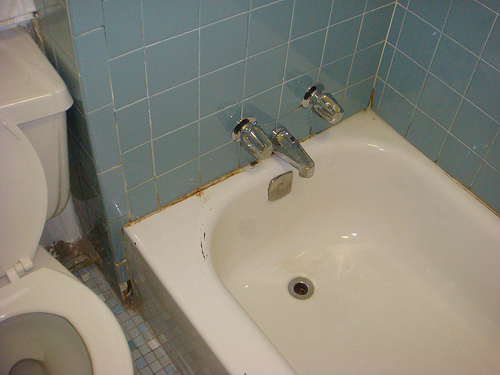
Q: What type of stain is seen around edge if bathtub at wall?
A: Rust.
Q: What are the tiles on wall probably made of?
A: Ceramic.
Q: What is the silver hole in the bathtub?
A: Drain.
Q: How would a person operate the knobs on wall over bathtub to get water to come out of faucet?
A: By turning.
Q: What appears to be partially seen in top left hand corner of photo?
A: Towel.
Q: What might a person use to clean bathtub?
A: Scouring powder.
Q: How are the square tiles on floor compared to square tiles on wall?
A: Smaller.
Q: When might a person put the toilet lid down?
A: To sit.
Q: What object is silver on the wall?
A: Spigot.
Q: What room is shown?
A: Bathroom.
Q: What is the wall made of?
A: Tile.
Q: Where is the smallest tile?
A: Floor.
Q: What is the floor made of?
A: Tile.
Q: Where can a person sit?
A: Toilet.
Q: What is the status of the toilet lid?
A: Raised.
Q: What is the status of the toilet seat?
A: Down.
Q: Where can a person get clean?
A: Tub.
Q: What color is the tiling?
A: Blue.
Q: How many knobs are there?
A: Two.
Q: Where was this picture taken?
A: Bathroom.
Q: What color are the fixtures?
A: Silver.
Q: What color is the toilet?
A: White.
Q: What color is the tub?
A: White.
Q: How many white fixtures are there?
A: Two.